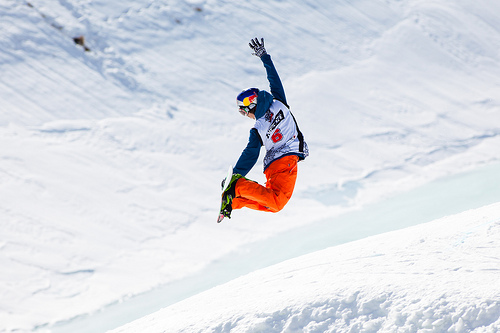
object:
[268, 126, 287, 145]
number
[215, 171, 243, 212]
shoes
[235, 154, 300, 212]
pants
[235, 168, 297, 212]
legs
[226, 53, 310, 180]
coat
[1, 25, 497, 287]
mountain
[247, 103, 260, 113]
eyeglass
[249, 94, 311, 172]
top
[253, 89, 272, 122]
hood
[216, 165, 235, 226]
snow board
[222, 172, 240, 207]
feet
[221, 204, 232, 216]
feet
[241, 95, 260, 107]
logo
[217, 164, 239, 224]
snowboard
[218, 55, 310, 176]
jacket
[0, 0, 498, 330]
snow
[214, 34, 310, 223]
man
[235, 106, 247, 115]
goggles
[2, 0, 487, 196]
hill side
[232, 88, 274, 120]
helmet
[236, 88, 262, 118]
head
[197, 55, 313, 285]
snowboarder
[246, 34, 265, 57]
glove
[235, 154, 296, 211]
orange pants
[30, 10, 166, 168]
hill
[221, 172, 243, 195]
hand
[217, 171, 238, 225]
board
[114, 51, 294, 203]
air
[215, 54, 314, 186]
person